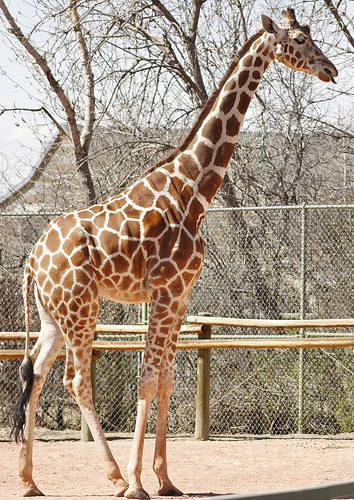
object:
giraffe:
[7, 3, 338, 499]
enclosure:
[0, 200, 354, 499]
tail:
[6, 267, 41, 449]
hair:
[5, 356, 40, 447]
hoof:
[154, 480, 183, 496]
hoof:
[121, 483, 151, 499]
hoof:
[110, 474, 128, 498]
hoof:
[16, 478, 43, 498]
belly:
[96, 273, 153, 305]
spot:
[113, 271, 140, 294]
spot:
[125, 279, 144, 296]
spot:
[100, 277, 119, 293]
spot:
[118, 289, 134, 304]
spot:
[98, 258, 117, 280]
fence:
[1, 200, 354, 444]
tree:
[0, 0, 138, 432]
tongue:
[326, 69, 337, 86]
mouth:
[318, 66, 340, 88]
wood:
[1, 310, 354, 350]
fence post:
[194, 311, 209, 443]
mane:
[139, 18, 274, 196]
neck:
[177, 22, 281, 206]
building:
[0, 120, 353, 430]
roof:
[0, 117, 352, 209]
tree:
[21, 2, 353, 334]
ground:
[0, 432, 352, 500]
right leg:
[59, 327, 131, 499]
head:
[258, 4, 343, 90]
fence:
[1, 311, 353, 440]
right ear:
[257, 12, 280, 37]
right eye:
[295, 35, 308, 48]